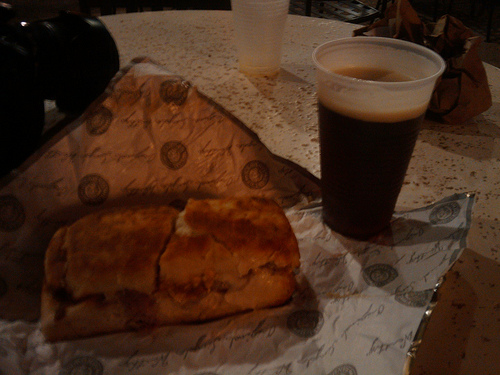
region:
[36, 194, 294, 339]
sandwich cut in half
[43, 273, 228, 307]
meat inside top and bottom bread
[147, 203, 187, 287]
cut in middle of sandwich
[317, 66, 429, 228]
ale in plastic cup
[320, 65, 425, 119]
foamy head on ale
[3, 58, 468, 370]
wrinkled paper under sandwich and cup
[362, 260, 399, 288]
circle design on paper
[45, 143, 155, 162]
words in cursive on paper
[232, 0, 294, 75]
empty cup on table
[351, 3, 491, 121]
crumpled brown paper bag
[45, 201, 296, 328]
toasted sub on paper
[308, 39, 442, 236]
disposable plastic cup on table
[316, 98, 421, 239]
dark cola in cup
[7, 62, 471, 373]
white aluminum food wrapper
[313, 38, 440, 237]
cola and ice in cup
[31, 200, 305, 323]
sandwich on aluminum wrap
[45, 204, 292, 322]
deli sandwich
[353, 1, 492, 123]
brown paper bag on table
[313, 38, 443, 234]
a drink in a plastic cup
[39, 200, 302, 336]
a sandwich on foil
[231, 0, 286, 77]
an empty plastic cup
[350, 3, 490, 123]
a crumpled paper bag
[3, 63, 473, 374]
a piece of foil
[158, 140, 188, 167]
a grey circular logo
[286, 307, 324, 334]
a grey circular logo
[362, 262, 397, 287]
a grey circular logo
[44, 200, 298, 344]
a biscuit sandwich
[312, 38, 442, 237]
cup of dark brown liquid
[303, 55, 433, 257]
the cup has liquid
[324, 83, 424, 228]
the cup is plastic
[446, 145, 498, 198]
the table is ceramic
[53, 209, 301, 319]
the cake has cracks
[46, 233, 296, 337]
the cake is brown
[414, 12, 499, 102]
the paper is brown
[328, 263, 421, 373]
the foil has letters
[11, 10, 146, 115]
camera is on the table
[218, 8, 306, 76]
the cup is plastic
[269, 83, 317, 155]
bread crumbs are on the surface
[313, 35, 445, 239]
The cup is made of plastic.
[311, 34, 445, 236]
The cup is clear.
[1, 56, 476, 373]
The sandwich is on paper.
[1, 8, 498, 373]
The table is white.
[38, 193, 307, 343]
A sandwich.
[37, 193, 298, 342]
The bread is brown.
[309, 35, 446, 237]
The cup is full.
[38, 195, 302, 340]
The sandwich is thick.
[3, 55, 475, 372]
The paper is white.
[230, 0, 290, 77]
Another cup is in the background.